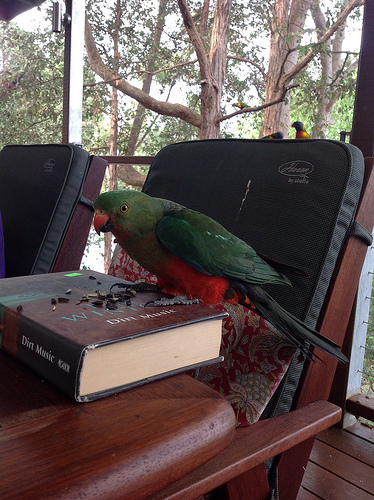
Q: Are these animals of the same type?
A: Yes, all the animals are birds.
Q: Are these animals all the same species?
A: Yes, all the animals are birds.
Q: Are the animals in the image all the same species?
A: Yes, all the animals are birds.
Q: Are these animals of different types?
A: No, all the animals are birds.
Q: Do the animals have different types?
A: No, all the animals are birds.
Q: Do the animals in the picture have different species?
A: No, all the animals are birds.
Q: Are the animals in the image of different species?
A: No, all the animals are birds.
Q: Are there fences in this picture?
A: No, there are no fences.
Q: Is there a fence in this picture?
A: No, there are no fences.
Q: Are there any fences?
A: No, there are no fences.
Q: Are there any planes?
A: No, there are no planes.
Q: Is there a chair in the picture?
A: Yes, there is a chair.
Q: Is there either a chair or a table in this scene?
A: Yes, there is a chair.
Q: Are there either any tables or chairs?
A: Yes, there is a chair.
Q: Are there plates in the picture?
A: No, there are no plates.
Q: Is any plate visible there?
A: No, there are no plates.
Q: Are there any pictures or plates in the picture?
A: No, there are no plates or pictures.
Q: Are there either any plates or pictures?
A: No, there are no plates or pictures.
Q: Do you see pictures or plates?
A: No, there are no plates or pictures.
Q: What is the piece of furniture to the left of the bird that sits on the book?
A: The piece of furniture is a chair.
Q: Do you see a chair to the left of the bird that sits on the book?
A: Yes, there is a chair to the left of the bird.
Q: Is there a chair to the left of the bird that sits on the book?
A: Yes, there is a chair to the left of the bird.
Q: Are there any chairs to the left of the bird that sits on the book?
A: Yes, there is a chair to the left of the bird.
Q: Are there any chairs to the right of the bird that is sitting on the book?
A: No, the chair is to the left of the bird.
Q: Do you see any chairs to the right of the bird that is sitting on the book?
A: No, the chair is to the left of the bird.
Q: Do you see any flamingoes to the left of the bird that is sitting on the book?
A: No, there is a chair to the left of the bird.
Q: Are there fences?
A: No, there are no fences.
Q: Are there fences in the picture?
A: No, there are no fences.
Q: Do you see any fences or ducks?
A: No, there are no fences or ducks.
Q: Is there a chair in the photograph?
A: Yes, there is a chair.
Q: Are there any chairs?
A: Yes, there is a chair.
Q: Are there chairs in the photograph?
A: Yes, there is a chair.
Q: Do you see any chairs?
A: Yes, there is a chair.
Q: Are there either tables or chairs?
A: Yes, there is a chair.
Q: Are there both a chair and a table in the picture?
A: Yes, there are both a chair and a table.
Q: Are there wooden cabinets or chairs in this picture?
A: Yes, there is a wood chair.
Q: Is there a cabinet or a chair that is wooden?
A: Yes, the chair is wooden.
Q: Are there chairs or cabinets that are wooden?
A: Yes, the chair is wooden.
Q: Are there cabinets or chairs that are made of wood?
A: Yes, the chair is made of wood.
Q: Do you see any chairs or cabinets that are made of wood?
A: Yes, the chair is made of wood.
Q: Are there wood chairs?
A: Yes, there is a chair that is made of wood.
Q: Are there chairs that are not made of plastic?
A: Yes, there is a chair that is made of wood.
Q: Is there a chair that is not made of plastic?
A: Yes, there is a chair that is made of wood.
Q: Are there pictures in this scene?
A: No, there are no pictures.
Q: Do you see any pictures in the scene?
A: No, there are no pictures.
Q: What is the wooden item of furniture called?
A: The piece of furniture is a chair.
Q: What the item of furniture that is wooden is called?
A: The piece of furniture is a chair.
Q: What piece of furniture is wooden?
A: The piece of furniture is a chair.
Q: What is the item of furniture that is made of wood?
A: The piece of furniture is a chair.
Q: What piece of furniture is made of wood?
A: The piece of furniture is a chair.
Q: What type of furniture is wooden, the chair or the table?
A: The chair is wooden.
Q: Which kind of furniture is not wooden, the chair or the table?
A: The table is not wooden.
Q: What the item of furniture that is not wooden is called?
A: The piece of furniture is a table.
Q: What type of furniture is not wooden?
A: The furniture is a table.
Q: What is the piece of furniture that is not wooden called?
A: The piece of furniture is a table.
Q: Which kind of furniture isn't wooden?
A: The furniture is a table.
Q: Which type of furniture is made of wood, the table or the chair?
A: The chair is made of wood.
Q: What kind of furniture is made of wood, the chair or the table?
A: The chair is made of wood.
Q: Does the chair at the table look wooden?
A: Yes, the chair is wooden.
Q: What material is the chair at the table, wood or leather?
A: The chair is made of wood.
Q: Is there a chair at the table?
A: Yes, there is a chair at the table.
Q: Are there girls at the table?
A: No, there is a chair at the table.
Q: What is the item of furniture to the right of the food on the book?
A: The piece of furniture is a chair.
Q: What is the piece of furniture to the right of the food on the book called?
A: The piece of furniture is a chair.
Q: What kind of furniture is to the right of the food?
A: The piece of furniture is a chair.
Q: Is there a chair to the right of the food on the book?
A: Yes, there is a chair to the right of the food.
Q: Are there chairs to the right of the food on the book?
A: Yes, there is a chair to the right of the food.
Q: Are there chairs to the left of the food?
A: No, the chair is to the right of the food.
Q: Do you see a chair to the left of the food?
A: No, the chair is to the right of the food.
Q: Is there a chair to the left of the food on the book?
A: No, the chair is to the right of the food.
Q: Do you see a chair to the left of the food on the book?
A: No, the chair is to the right of the food.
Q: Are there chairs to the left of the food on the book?
A: No, the chair is to the right of the food.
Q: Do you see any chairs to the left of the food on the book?
A: No, the chair is to the right of the food.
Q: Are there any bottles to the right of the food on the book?
A: No, there is a chair to the right of the food.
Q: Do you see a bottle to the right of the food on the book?
A: No, there is a chair to the right of the food.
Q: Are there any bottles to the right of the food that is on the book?
A: No, there is a chair to the right of the food.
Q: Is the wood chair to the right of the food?
A: Yes, the chair is to the right of the food.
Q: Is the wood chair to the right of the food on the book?
A: Yes, the chair is to the right of the food.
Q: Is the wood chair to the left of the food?
A: No, the chair is to the right of the food.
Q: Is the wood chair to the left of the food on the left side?
A: No, the chair is to the right of the food.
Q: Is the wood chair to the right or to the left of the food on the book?
A: The chair is to the right of the food.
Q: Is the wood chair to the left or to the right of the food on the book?
A: The chair is to the right of the food.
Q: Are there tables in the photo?
A: Yes, there is a table.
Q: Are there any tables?
A: Yes, there is a table.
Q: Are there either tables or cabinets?
A: Yes, there is a table.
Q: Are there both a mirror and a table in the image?
A: No, there is a table but no mirrors.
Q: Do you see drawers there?
A: No, there are no drawers.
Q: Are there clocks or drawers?
A: No, there are no drawers or clocks.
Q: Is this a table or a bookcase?
A: This is a table.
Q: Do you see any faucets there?
A: No, there are no faucets.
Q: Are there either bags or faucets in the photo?
A: No, there are no faucets or bags.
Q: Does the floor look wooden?
A: Yes, the floor is wooden.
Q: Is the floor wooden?
A: Yes, the floor is wooden.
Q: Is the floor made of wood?
A: Yes, the floor is made of wood.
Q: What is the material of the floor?
A: The floor is made of wood.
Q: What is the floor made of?
A: The floor is made of wood.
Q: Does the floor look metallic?
A: No, the floor is wooden.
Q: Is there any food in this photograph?
A: Yes, there is food.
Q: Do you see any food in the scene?
A: Yes, there is food.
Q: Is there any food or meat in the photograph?
A: Yes, there is food.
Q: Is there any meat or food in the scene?
A: Yes, there is food.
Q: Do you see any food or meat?
A: Yes, there is food.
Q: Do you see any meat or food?
A: Yes, there is food.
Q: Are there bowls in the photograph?
A: No, there are no bowls.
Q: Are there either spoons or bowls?
A: No, there are no bowls or spoons.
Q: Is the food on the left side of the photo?
A: Yes, the food is on the left of the image.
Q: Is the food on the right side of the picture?
A: No, the food is on the left of the image.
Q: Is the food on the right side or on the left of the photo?
A: The food is on the left of the image.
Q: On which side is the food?
A: The food is on the left of the image.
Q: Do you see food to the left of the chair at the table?
A: Yes, there is food to the left of the chair.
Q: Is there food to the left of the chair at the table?
A: Yes, there is food to the left of the chair.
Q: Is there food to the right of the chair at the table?
A: No, the food is to the left of the chair.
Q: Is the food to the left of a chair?
A: Yes, the food is to the left of a chair.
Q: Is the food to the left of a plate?
A: No, the food is to the left of a chair.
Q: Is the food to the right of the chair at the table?
A: No, the food is to the left of the chair.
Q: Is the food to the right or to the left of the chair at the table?
A: The food is to the left of the chair.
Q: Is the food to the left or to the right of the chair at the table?
A: The food is to the left of the chair.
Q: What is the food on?
A: The food is on the book.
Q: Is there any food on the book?
A: Yes, there is food on the book.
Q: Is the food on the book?
A: Yes, the food is on the book.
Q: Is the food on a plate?
A: No, the food is on the book.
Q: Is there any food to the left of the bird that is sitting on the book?
A: Yes, there is food to the left of the bird.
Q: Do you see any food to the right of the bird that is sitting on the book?
A: No, the food is to the left of the bird.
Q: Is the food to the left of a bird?
A: Yes, the food is to the left of a bird.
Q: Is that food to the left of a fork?
A: No, the food is to the left of a bird.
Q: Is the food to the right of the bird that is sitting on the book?
A: No, the food is to the left of the bird.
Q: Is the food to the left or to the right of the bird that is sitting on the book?
A: The food is to the left of the bird.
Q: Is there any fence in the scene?
A: No, there are no fences.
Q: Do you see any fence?
A: No, there are no fences.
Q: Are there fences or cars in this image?
A: No, there are no fences or cars.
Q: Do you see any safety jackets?
A: No, there are no safety jackets.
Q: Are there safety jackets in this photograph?
A: No, there are no safety jackets.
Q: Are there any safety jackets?
A: No, there are no safety jackets.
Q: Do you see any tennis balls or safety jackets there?
A: No, there are no safety jackets or tennis balls.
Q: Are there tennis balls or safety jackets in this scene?
A: No, there are no safety jackets or tennis balls.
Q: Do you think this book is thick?
A: Yes, the book is thick.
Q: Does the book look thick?
A: Yes, the book is thick.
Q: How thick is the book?
A: The book is thick.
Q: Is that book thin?
A: No, the book is thick.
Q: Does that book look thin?
A: No, the book is thick.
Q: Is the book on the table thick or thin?
A: The book is thick.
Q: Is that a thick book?
A: Yes, that is a thick book.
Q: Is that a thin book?
A: No, that is a thick book.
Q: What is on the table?
A: The book is on the table.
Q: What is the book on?
A: The book is on the table.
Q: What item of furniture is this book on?
A: The book is on the table.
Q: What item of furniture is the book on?
A: The book is on the table.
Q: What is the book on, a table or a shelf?
A: The book is on a table.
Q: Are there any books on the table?
A: Yes, there is a book on the table.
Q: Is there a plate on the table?
A: No, there is a book on the table.